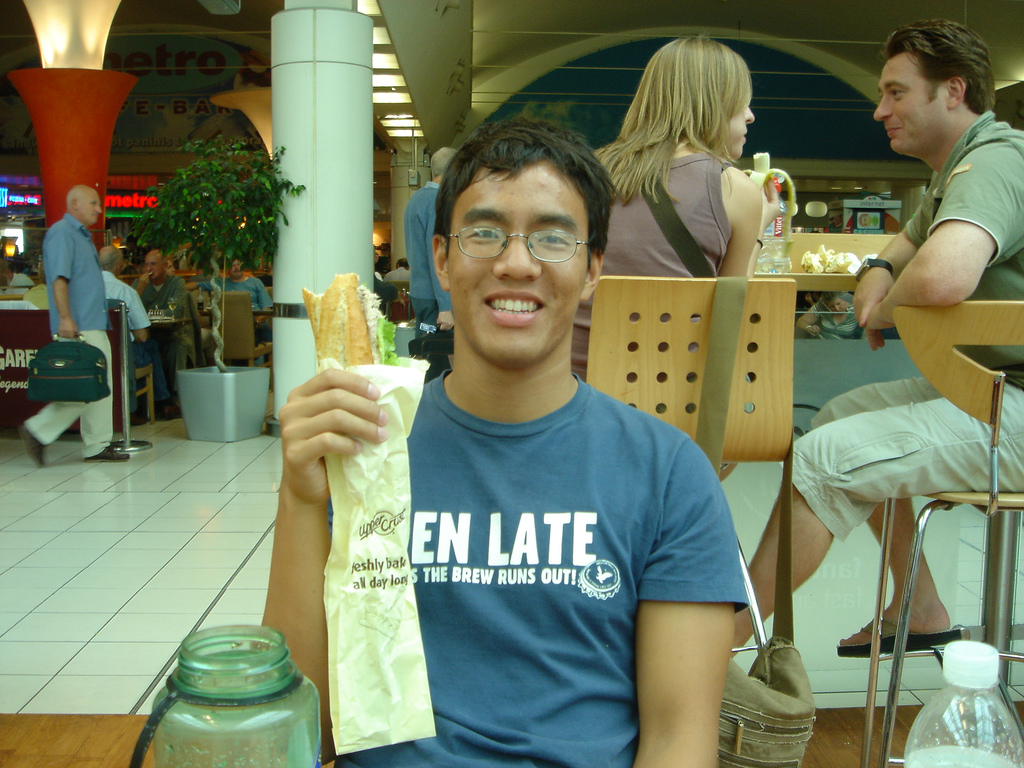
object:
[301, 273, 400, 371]
sandwich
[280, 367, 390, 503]
hand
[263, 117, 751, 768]
boy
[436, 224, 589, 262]
glasses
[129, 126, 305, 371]
planter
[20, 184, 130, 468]
man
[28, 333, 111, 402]
bag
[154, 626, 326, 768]
jar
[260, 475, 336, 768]
arm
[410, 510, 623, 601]
writing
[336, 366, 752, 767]
shirt